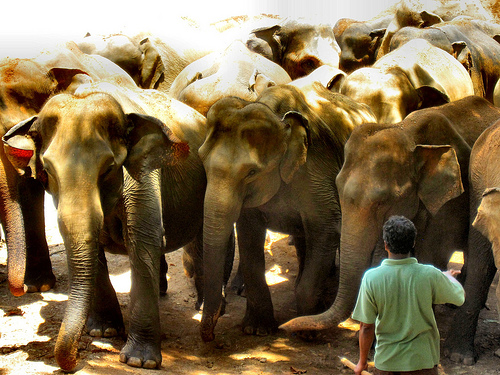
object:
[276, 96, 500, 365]
elephants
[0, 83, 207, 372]
elephant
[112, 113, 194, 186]
ears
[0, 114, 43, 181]
ears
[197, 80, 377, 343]
elephants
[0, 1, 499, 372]
group